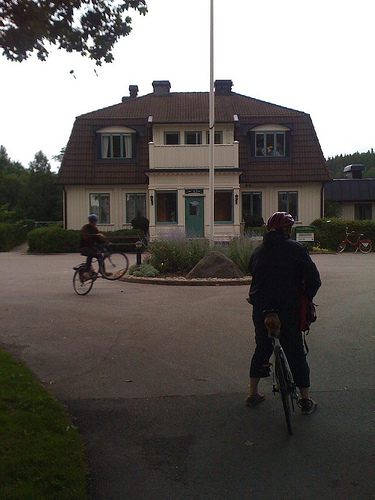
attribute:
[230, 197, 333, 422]
woman — stopped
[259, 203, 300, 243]
helmet — blue, red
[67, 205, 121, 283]
boy — popping, wheeling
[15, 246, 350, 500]
sidewalk — paved, concrete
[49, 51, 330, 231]
house — yellow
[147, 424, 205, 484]
stain — oil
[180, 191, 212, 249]
door — green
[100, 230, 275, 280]
flower bed — various, round, large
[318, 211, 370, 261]
bike — red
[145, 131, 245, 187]
balcony — beige, second story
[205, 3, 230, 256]
pole — tall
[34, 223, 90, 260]
bush — green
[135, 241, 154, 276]
sign — white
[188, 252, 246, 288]
rock — large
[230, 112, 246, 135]
light — outdoor